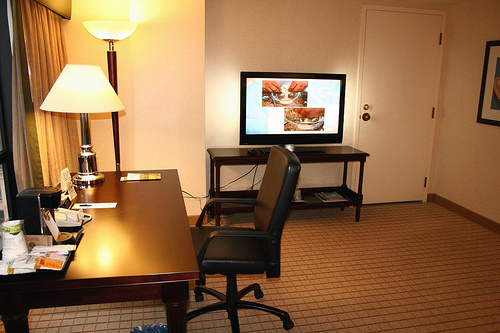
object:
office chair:
[190, 145, 302, 333]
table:
[1, 169, 203, 333]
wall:
[68, 0, 445, 210]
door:
[350, 2, 443, 206]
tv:
[238, 71, 347, 145]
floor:
[14, 201, 500, 332]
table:
[206, 145, 369, 227]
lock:
[362, 103, 372, 122]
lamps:
[80, 19, 140, 176]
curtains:
[1, 1, 91, 192]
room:
[0, 0, 498, 332]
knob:
[361, 104, 371, 122]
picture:
[476, 39, 500, 127]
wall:
[434, 2, 498, 229]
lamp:
[38, 63, 126, 187]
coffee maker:
[17, 186, 77, 247]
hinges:
[422, 25, 445, 202]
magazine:
[312, 191, 349, 203]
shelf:
[211, 186, 362, 212]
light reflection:
[71, 212, 133, 276]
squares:
[274, 206, 500, 332]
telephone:
[47, 207, 93, 227]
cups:
[1, 221, 28, 264]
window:
[4, 9, 62, 218]